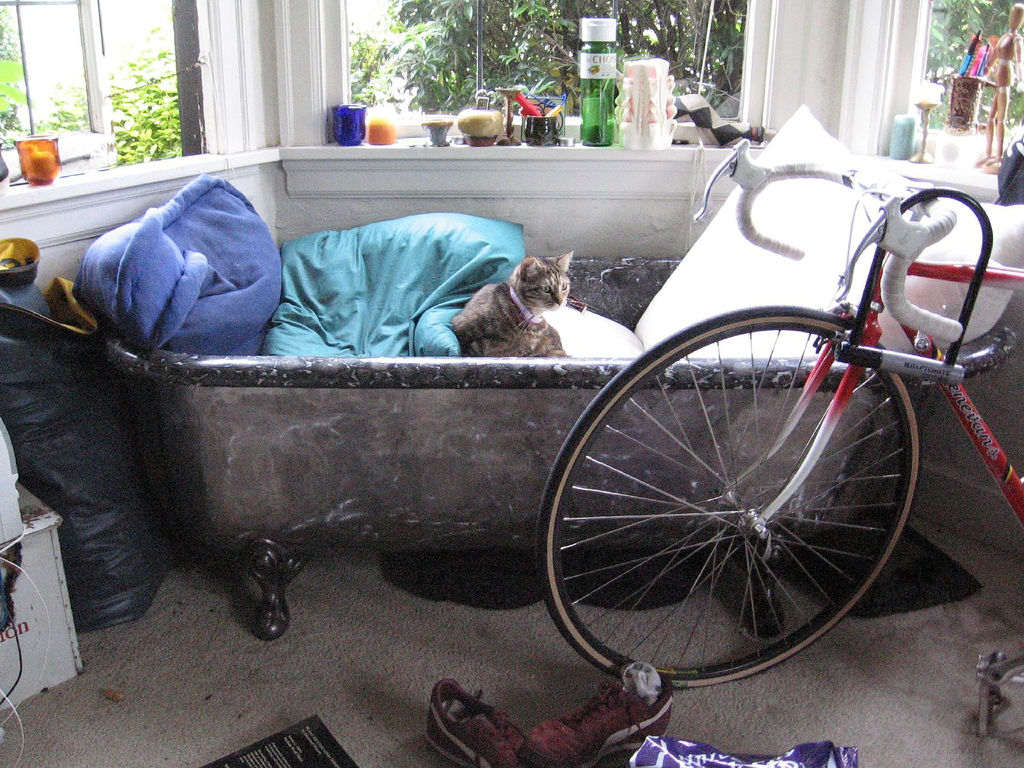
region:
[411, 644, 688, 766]
The mans shoes on the ground.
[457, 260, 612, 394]
The tan cat.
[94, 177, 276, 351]
The blue pillow in the tub.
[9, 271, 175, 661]
The large bag on the left.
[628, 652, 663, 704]
The sock in the shoe.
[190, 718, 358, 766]
The black book on the floor.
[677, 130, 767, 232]
brakes on the bike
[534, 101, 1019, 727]
a red road bike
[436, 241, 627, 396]
a cat laying in a tub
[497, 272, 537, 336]
a purple collar on the cat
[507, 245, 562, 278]
ear of the cat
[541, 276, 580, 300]
eyes of the cat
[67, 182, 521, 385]
blue pillows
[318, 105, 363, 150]
object on the windowsill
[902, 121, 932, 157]
object on the windowsill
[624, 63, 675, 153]
object on the windowsill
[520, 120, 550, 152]
object on the windowsill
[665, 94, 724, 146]
object on the windowsill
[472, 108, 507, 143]
object on the windowsill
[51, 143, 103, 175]
object on the windowsill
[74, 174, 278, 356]
the pillow is blue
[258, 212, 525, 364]
the pillow is aqua blue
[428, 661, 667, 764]
the shoes are maroon and white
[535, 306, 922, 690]
the tire is large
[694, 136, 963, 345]
the handlebars are white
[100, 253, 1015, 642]
the claw tub is gray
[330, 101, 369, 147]
the cup is blue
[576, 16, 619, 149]
the bottle is green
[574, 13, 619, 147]
the white cap on the green bottle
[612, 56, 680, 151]
the decorative candle is large and white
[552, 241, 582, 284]
ear of the cat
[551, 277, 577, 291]
eye of the cat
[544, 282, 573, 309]
nose of the cat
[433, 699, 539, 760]
shoe on the floor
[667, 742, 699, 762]
shoe on the floor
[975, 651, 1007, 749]
shoe on the floor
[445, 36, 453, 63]
A leaf on a stem.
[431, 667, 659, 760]
a pair of maroon and white tennis shoes on floor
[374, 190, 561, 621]
cat sitting in claw foot tub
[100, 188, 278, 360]
blue pillow inside the claw foot tub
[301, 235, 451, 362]
teal colored pillow in claw foot tub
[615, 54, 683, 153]
large white and pink candle in windowsill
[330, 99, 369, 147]
royal blue candle holder on windowsill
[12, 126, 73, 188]
orange candle holder on windowsill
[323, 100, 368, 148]
nick knack on the window sill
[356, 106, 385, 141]
nick knack on the window sill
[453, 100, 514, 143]
nick knack on the window sill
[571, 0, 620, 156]
nick knack on the window sill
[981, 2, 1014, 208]
nick knack on the window sill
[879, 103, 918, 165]
nick knack on the window sill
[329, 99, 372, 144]
the cup is made of blue glass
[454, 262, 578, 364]
a cat is on the tub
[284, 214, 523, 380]
the cushion is on the tub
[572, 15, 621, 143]
the bottle is green in color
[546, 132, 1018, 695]
a bicycle is in the room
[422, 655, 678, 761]
shoes are on the floor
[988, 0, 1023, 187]
a wood figure is on the window sill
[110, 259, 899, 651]
a tub is in the room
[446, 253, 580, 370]
the cat is grey in color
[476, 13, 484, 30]
green leaves on the treegreen leaves on the tree